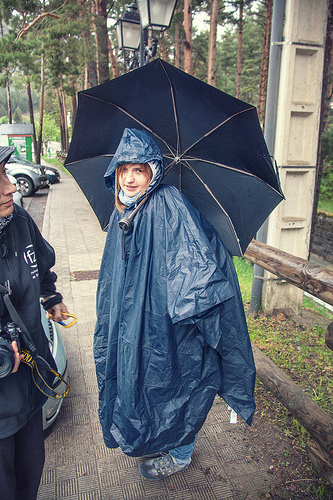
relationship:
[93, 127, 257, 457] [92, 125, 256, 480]
raincoat on girl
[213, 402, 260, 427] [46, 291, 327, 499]
garbage on ground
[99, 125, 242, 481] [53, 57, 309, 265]
girl holding umbrella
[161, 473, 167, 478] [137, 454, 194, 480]
edge of shoe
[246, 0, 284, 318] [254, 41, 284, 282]
clips attached with clips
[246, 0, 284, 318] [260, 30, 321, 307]
clips attached to column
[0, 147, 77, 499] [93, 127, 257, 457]
man wearing raincoat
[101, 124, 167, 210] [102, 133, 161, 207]
hood covering head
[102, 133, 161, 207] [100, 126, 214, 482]
head of woman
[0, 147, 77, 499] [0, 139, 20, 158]
man wearing hat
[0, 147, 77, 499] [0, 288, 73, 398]
man holding camera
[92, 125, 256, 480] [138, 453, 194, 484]
girl wearing shoe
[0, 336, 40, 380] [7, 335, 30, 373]
camera in person's hand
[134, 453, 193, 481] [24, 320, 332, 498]
shoe on ground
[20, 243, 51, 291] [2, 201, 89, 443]
logo on jacket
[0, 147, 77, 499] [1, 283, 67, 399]
man holding camera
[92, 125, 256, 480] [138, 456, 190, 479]
girl wearing shoes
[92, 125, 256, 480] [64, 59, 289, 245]
girl holding umbrella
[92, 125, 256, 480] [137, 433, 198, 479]
girl wearing jeans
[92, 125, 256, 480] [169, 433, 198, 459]
girl wearing jeans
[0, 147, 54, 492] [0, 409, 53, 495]
man wearing pants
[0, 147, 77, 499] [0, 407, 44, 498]
man wearing pants